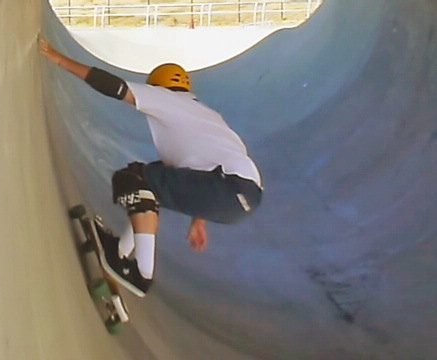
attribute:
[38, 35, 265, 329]
boy — skateboarding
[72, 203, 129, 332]
skateboard — wooden, black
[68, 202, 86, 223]
wheel — rubber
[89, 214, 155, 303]
shoes — black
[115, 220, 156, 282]
socks — white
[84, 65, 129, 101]
elbow pads — black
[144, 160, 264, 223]
shorts — blue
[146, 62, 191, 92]
helmet — yellow, orange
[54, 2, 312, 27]
rails — metal, white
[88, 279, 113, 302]
wheel — green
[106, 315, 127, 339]
wheel — green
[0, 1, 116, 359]
wall — grey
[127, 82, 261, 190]
shirt — white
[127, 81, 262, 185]
man — skating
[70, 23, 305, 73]
ground — gray